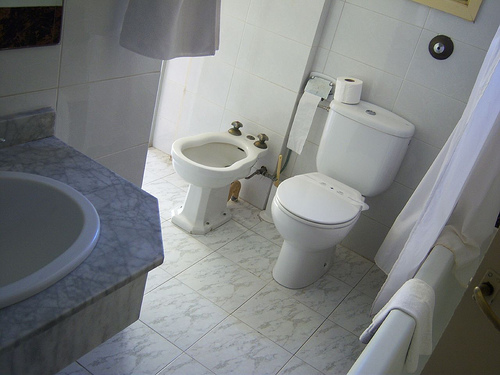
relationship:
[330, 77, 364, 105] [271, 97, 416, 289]
paper on toilet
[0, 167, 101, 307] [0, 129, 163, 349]
sink on counter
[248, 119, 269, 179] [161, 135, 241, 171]
brass knob on white toilet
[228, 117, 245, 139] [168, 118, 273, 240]
knob on toilet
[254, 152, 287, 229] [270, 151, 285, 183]
toilet brush has handle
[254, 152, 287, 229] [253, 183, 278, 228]
toilet brush in container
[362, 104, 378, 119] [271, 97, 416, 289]
button on toilet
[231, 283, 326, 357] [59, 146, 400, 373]
tile on floor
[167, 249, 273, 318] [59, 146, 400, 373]
tile on floor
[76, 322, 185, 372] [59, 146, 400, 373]
tile on floor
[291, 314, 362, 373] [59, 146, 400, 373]
tile on floor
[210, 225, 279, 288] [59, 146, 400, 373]
tile on floor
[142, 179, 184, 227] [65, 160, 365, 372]
tile on floor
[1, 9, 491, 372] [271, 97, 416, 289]
bathroom has toilet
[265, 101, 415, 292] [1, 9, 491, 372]
toilet in bathroom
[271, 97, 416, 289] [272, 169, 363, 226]
toilet has lid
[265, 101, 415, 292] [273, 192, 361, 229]
toilet has seat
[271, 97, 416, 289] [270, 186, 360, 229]
toilet has seat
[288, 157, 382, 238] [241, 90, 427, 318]
seal on toilet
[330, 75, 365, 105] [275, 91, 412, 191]
paper on tank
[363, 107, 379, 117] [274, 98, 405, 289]
button on toilet